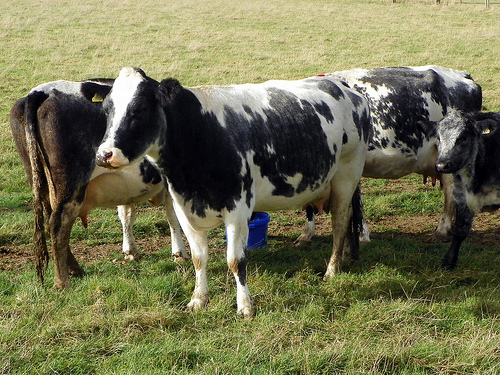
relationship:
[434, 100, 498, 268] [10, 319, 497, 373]
cow standing field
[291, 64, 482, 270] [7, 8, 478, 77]
cow standing field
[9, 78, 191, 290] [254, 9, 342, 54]
cow standing grass field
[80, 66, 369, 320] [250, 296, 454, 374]
cows standing field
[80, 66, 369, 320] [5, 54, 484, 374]
cows facing camera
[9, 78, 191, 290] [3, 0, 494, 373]
cow standing grass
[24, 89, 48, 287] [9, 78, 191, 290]
tail of cow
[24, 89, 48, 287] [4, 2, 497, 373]
tail goes to ground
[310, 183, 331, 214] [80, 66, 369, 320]
udder of cows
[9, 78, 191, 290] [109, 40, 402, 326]
cow next to cow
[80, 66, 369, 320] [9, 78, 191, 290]
cows next to cow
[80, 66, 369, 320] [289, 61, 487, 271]
cows next to cow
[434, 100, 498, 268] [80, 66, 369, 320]
cow next to cows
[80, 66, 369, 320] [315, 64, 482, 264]
cows in front of cow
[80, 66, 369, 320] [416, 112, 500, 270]
cows in front of cow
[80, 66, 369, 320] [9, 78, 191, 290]
cows in front of cow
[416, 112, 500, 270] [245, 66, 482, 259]
cow in front of cow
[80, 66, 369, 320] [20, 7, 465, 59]
cows in field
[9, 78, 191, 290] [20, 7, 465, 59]
cow in field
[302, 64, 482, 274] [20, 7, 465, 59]
cow in field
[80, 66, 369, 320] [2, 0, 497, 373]
cows in field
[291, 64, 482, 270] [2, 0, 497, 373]
cow in field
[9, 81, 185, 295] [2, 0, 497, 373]
cow in field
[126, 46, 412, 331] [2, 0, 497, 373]
cows in field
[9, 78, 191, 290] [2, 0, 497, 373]
cow in field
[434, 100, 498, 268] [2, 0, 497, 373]
cow in field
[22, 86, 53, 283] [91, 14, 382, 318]
tail of cow